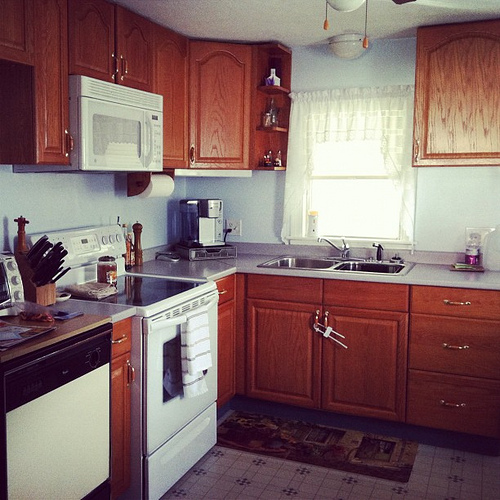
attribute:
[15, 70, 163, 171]
microwave — white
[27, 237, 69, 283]
knives — black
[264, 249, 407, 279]
sinks — silver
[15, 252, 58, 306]
knife block — wooden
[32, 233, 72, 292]
knives — black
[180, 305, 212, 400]
cloth — white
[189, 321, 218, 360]
towel — white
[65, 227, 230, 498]
dish washer — white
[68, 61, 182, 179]
microwave — white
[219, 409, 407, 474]
runner — brown